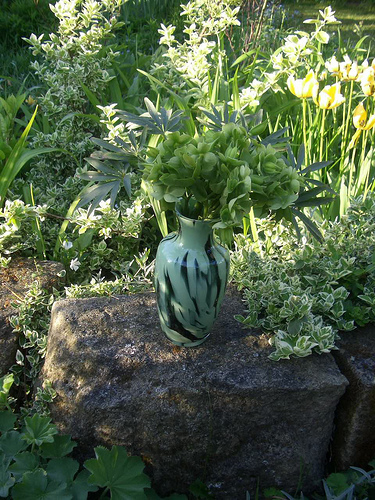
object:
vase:
[153, 220, 232, 346]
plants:
[181, 152, 201, 215]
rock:
[47, 299, 345, 492]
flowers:
[312, 81, 347, 111]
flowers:
[287, 68, 320, 100]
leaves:
[157, 29, 165, 35]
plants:
[32, 132, 50, 144]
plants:
[189, 67, 209, 92]